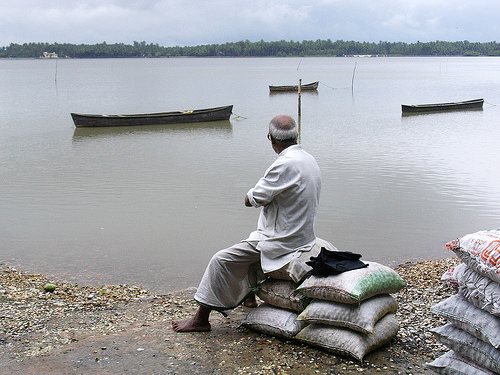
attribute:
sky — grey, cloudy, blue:
[1, 0, 500, 48]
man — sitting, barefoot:
[171, 114, 325, 333]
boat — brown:
[70, 102, 237, 130]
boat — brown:
[266, 80, 322, 93]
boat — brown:
[400, 96, 487, 116]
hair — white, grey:
[267, 120, 298, 142]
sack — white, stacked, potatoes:
[293, 258, 406, 304]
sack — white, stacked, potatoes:
[297, 292, 399, 336]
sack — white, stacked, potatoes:
[293, 312, 402, 362]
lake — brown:
[1, 57, 499, 287]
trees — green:
[0, 40, 499, 59]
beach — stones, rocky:
[1, 258, 466, 374]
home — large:
[38, 49, 61, 60]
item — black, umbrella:
[304, 245, 370, 280]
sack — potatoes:
[237, 302, 306, 341]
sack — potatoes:
[253, 276, 310, 313]